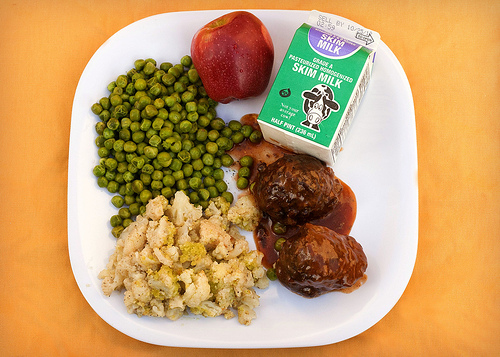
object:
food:
[88, 9, 369, 326]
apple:
[189, 10, 274, 104]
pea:
[180, 55, 192, 68]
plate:
[65, 7, 420, 351]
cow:
[300, 83, 341, 132]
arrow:
[355, 31, 375, 45]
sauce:
[321, 206, 355, 235]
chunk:
[236, 304, 257, 326]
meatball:
[271, 222, 369, 300]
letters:
[288, 54, 354, 88]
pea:
[142, 61, 157, 75]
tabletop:
[0, 0, 76, 89]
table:
[0, 0, 500, 357]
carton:
[256, 9, 381, 166]